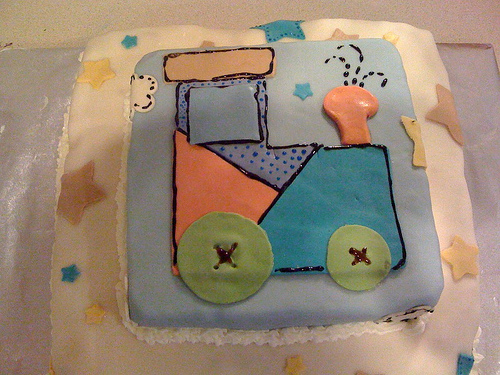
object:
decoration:
[126, 39, 448, 337]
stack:
[322, 85, 425, 145]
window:
[183, 83, 264, 146]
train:
[161, 44, 407, 306]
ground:
[464, 130, 500, 159]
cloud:
[131, 73, 157, 113]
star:
[432, 232, 487, 287]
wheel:
[324, 222, 394, 293]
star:
[248, 19, 307, 45]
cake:
[48, 18, 481, 374]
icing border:
[119, 306, 428, 349]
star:
[75, 57, 118, 91]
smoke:
[322, 42, 391, 88]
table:
[0, 0, 499, 375]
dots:
[301, 149, 307, 155]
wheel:
[174, 208, 275, 307]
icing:
[45, 18, 483, 375]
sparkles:
[247, 18, 308, 44]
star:
[290, 82, 315, 102]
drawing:
[158, 45, 426, 308]